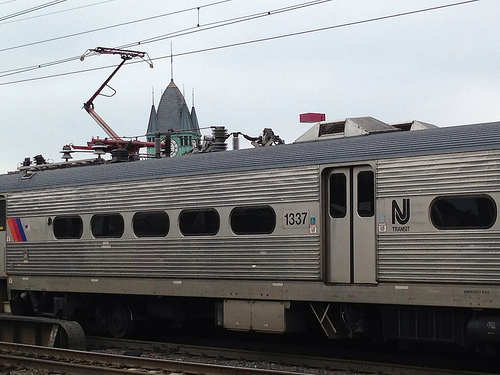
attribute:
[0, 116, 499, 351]
train — silver, small, blue, side 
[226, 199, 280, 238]
window — oval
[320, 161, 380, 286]
door — closed, silver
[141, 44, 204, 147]
church roof — grey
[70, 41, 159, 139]
equipment — red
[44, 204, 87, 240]
window — small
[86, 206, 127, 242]
window — small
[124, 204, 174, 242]
window — small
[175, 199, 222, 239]
window — small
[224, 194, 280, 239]
window — small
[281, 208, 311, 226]
numbers — black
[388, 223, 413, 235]
letter — black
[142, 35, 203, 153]
tower — tall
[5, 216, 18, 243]
color — orange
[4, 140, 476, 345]
car — Train 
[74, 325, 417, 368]
tracks — railroad 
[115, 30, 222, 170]
tower — Green clock , distance. 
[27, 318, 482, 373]
tracks — Railroad. 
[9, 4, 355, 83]
cables — Electric 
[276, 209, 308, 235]
number — black , 1337 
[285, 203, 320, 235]
number — black 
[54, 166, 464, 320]
train — row , side 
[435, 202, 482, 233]
windows — tinted 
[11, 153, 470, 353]
train — side 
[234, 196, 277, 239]
window — tinted 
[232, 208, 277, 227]
window — tinted 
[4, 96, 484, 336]
train — side 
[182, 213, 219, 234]
window — tinted 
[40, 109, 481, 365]
train — silver 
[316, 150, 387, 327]
door — silver 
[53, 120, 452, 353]
train — black 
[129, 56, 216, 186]
tower — blue 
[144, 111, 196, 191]
clock — white , round 